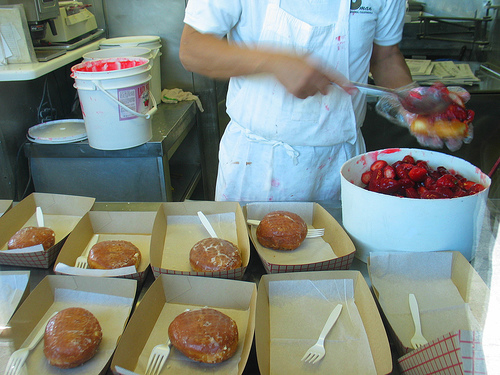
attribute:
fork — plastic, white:
[301, 300, 345, 365]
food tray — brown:
[152, 198, 253, 277]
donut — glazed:
[187, 238, 246, 273]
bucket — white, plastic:
[335, 144, 494, 253]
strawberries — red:
[366, 163, 442, 192]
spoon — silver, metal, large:
[359, 76, 448, 118]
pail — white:
[338, 149, 492, 250]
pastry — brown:
[89, 241, 141, 266]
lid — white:
[27, 119, 88, 144]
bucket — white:
[69, 59, 155, 153]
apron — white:
[221, 0, 358, 205]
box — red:
[417, 332, 481, 373]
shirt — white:
[179, 0, 403, 139]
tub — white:
[337, 145, 495, 243]